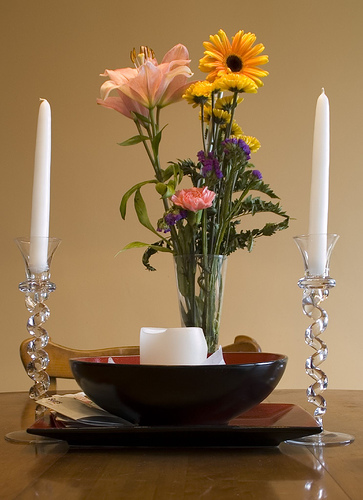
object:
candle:
[307, 88, 329, 276]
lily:
[96, 43, 202, 128]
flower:
[221, 137, 251, 160]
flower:
[253, 169, 263, 179]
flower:
[201, 159, 223, 181]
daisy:
[198, 28, 270, 91]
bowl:
[68, 352, 288, 425]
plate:
[25, 403, 322, 450]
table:
[1, 390, 361, 499]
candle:
[29, 97, 51, 274]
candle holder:
[282, 231, 354, 448]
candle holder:
[5, 236, 62, 445]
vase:
[171, 254, 229, 354]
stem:
[140, 111, 180, 254]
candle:
[139, 326, 208, 366]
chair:
[19, 334, 261, 397]